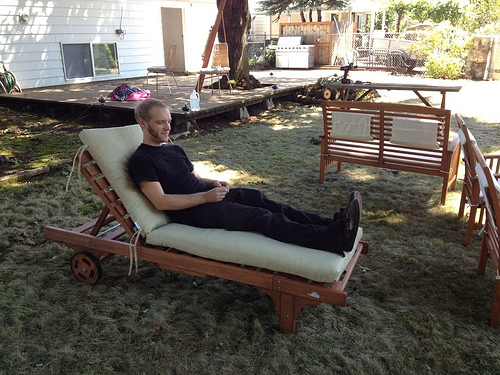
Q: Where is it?
A: This is at the lounge.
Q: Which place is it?
A: It is a lounge.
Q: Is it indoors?
A: Yes, it is indoors.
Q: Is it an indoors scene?
A: Yes, it is indoors.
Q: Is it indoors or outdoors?
A: It is indoors.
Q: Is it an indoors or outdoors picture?
A: It is indoors.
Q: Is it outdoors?
A: No, it is indoors.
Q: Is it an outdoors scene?
A: No, it is indoors.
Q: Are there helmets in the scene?
A: No, there are no helmets.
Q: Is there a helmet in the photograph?
A: No, there are no helmets.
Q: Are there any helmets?
A: No, there are no helmets.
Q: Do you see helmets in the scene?
A: No, there are no helmets.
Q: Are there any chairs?
A: Yes, there is a chair.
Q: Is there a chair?
A: Yes, there is a chair.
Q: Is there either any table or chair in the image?
A: Yes, there is a chair.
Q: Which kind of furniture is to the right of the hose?
A: The piece of furniture is a chair.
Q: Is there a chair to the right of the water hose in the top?
A: Yes, there is a chair to the right of the water hose.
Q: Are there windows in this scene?
A: Yes, there is a window.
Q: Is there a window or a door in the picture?
A: Yes, there is a window.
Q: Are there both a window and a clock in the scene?
A: No, there is a window but no clocks.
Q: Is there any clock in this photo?
A: No, there are no clocks.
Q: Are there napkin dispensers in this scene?
A: No, there are no napkin dispensers.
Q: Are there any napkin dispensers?
A: No, there are no napkin dispensers.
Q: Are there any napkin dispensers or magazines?
A: No, there are no napkin dispensers or magazines.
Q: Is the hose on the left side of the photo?
A: Yes, the hose is on the left of the image.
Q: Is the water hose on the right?
A: No, the water hose is on the left of the image.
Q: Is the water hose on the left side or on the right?
A: The water hose is on the left of the image.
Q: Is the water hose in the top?
A: Yes, the water hose is in the top of the image.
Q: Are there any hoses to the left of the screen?
A: Yes, there is a hose to the left of the screen.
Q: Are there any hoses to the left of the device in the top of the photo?
A: Yes, there is a hose to the left of the screen.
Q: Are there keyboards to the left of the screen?
A: No, there is a hose to the left of the screen.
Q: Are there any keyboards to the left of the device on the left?
A: No, there is a hose to the left of the screen.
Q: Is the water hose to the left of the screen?
A: Yes, the water hose is to the left of the screen.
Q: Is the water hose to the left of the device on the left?
A: Yes, the water hose is to the left of the screen.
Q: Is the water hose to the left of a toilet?
A: No, the water hose is to the left of the screen.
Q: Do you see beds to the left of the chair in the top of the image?
A: No, there is a hose to the left of the chair.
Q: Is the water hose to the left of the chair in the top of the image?
A: Yes, the water hose is to the left of the chair.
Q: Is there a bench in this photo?
A: Yes, there is a bench.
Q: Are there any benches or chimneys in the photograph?
A: Yes, there is a bench.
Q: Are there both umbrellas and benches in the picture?
A: No, there is a bench but no umbrellas.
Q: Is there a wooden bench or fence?
A: Yes, there is a wood bench.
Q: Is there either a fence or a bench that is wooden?
A: Yes, the bench is wooden.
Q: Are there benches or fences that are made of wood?
A: Yes, the bench is made of wood.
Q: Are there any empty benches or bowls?
A: Yes, there is an empty bench.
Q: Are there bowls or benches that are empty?
A: Yes, the bench is empty.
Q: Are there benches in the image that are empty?
A: Yes, there is an empty bench.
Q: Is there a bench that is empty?
A: Yes, there is a bench that is empty.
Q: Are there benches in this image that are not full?
A: Yes, there is a empty bench.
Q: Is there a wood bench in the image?
A: Yes, there is a wood bench.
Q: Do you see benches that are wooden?
A: Yes, there is a bench that is wooden.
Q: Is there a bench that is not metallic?
A: Yes, there is a wooden bench.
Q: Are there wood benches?
A: Yes, there is a bench that is made of wood.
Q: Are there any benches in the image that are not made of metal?
A: Yes, there is a bench that is made of wood.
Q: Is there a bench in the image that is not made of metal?
A: Yes, there is a bench that is made of wood.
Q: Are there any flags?
A: No, there are no flags.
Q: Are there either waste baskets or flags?
A: No, there are no flags or waste baskets.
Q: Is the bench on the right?
A: Yes, the bench is on the right of the image.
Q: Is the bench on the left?
A: No, the bench is on the right of the image.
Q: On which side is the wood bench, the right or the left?
A: The bench is on the right of the image.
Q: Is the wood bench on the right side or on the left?
A: The bench is on the right of the image.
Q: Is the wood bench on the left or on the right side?
A: The bench is on the right of the image.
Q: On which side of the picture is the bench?
A: The bench is on the right of the image.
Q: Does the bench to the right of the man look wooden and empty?
A: Yes, the bench is wooden and empty.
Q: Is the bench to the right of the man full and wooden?
A: No, the bench is wooden but empty.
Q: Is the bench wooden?
A: Yes, the bench is wooden.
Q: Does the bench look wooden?
A: Yes, the bench is wooden.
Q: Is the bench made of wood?
A: Yes, the bench is made of wood.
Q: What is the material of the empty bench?
A: The bench is made of wood.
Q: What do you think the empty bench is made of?
A: The bench is made of wood.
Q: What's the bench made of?
A: The bench is made of wood.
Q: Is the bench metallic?
A: No, the bench is wooden.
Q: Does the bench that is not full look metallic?
A: No, the bench is wooden.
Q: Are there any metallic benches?
A: No, there is a bench but it is wooden.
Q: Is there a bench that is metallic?
A: No, there is a bench but it is wooden.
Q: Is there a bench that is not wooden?
A: No, there is a bench but it is wooden.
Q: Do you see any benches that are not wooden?
A: No, there is a bench but it is wooden.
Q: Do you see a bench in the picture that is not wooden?
A: No, there is a bench but it is wooden.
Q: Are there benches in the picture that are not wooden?
A: No, there is a bench but it is wooden.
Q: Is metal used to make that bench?
A: No, the bench is made of wood.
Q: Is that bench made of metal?
A: No, the bench is made of wood.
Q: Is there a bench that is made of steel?
A: No, there is a bench but it is made of wood.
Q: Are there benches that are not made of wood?
A: No, there is a bench but it is made of wood.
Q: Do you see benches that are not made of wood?
A: No, there is a bench but it is made of wood.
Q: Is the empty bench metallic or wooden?
A: The bench is wooden.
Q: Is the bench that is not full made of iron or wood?
A: The bench is made of wood.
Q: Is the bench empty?
A: Yes, the bench is empty.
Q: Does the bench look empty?
A: Yes, the bench is empty.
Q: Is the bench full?
A: No, the bench is empty.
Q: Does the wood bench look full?
A: No, the bench is empty.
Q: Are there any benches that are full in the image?
A: No, there is a bench but it is empty.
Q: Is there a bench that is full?
A: No, there is a bench but it is empty.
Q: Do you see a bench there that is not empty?
A: No, there is a bench but it is empty.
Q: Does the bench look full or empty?
A: The bench is empty.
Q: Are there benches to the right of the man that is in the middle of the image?
A: Yes, there is a bench to the right of the man.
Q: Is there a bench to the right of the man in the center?
A: Yes, there is a bench to the right of the man.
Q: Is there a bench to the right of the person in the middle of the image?
A: Yes, there is a bench to the right of the man.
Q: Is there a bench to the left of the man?
A: No, the bench is to the right of the man.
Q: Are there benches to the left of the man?
A: No, the bench is to the right of the man.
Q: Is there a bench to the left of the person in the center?
A: No, the bench is to the right of the man.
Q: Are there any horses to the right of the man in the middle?
A: No, there is a bench to the right of the man.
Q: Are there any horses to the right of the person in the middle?
A: No, there is a bench to the right of the man.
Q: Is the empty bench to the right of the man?
A: Yes, the bench is to the right of the man.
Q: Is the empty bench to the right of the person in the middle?
A: Yes, the bench is to the right of the man.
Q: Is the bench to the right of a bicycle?
A: No, the bench is to the right of the man.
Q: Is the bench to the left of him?
A: No, the bench is to the right of a man.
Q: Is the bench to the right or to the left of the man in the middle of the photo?
A: The bench is to the right of the man.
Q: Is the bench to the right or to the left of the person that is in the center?
A: The bench is to the right of the man.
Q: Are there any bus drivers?
A: No, there are no bus drivers.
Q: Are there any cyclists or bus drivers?
A: No, there are no bus drivers or cyclists.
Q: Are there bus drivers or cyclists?
A: No, there are no bus drivers or cyclists.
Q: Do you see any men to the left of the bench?
A: Yes, there is a man to the left of the bench.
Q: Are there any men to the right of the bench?
A: No, the man is to the left of the bench.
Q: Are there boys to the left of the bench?
A: No, there is a man to the left of the bench.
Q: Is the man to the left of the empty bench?
A: Yes, the man is to the left of the bench.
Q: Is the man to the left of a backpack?
A: No, the man is to the left of the bench.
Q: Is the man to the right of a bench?
A: No, the man is to the left of a bench.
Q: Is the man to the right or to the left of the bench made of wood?
A: The man is to the left of the bench.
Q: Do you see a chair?
A: Yes, there is a chair.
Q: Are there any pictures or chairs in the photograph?
A: Yes, there is a chair.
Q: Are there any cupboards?
A: No, there are no cupboards.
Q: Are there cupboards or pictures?
A: No, there are no cupboards or pictures.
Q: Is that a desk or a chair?
A: That is a chair.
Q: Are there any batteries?
A: No, there are no batteries.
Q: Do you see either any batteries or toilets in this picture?
A: No, there are no batteries or toilets.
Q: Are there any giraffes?
A: No, there are no giraffes.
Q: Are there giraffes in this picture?
A: No, there are no giraffes.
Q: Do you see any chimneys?
A: No, there are no chimneys.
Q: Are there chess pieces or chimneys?
A: No, there are no chimneys or chess pieces.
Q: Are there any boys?
A: No, there are no boys.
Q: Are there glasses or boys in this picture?
A: No, there are no boys or glasses.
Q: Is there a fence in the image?
A: Yes, there is a fence.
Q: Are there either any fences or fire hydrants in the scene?
A: Yes, there is a fence.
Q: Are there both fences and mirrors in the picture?
A: No, there is a fence but no mirrors.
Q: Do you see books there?
A: No, there are no books.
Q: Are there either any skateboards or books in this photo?
A: No, there are no books or skateboards.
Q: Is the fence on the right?
A: Yes, the fence is on the right of the image.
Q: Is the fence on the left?
A: No, the fence is on the right of the image.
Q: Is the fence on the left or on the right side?
A: The fence is on the right of the image.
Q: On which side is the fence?
A: The fence is on the right of the image.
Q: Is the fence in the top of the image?
A: Yes, the fence is in the top of the image.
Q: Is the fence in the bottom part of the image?
A: No, the fence is in the top of the image.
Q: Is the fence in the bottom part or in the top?
A: The fence is in the top of the image.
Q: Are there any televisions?
A: No, there are no televisions.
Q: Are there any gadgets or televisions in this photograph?
A: No, there are no televisions or gadgets.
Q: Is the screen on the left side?
A: Yes, the screen is on the left of the image.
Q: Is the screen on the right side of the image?
A: No, the screen is on the left of the image.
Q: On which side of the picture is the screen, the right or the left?
A: The screen is on the left of the image.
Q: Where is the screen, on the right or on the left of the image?
A: The screen is on the left of the image.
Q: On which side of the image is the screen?
A: The screen is on the left of the image.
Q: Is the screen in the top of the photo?
A: Yes, the screen is in the top of the image.